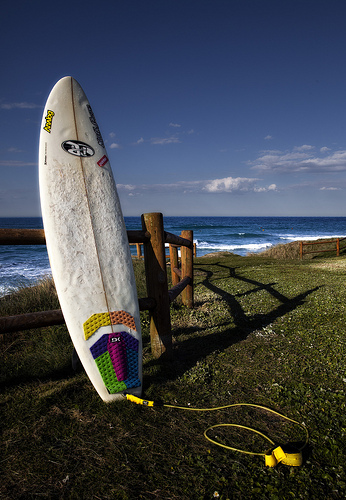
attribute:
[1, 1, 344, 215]
sky — dark blue, clear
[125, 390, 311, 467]
strap — yellow, foot strap, ankle strap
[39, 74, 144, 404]
surfboard — leaning, sitting, standing, white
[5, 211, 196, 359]
fence — wooden, brown, wood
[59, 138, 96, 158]
pattern — black, white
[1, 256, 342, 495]
grass — green, short, white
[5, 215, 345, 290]
water — light blue, blue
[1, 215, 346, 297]
waves — breaking, small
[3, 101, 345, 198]
clouds — white, fluffy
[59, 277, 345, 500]
flowers — white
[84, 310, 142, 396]
patches — colored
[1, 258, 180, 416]
grass — growing